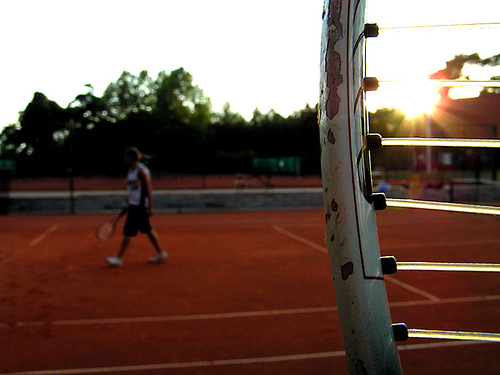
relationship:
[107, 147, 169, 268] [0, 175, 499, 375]
man on tennis court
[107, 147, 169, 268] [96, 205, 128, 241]
man has tennis racket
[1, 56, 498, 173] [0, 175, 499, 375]
trees behind tennis court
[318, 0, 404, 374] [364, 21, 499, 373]
pole has cables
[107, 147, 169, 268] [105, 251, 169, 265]
man has sneakers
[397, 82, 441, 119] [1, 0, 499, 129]
sun in sky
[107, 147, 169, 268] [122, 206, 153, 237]
man has shorts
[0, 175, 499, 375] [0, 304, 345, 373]
tennis court has white lines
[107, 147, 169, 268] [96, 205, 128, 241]
man holding tennis racket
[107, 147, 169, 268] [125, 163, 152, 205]
man wearing shirt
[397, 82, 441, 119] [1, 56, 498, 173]
sun behind trees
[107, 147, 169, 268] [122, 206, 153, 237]
man wearing shorts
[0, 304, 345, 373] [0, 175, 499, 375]
white lines on tennis court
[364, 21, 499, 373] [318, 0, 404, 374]
cables hooked to pole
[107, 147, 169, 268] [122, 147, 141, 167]
man has head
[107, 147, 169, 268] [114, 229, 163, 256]
man has legs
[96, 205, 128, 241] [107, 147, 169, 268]
tennis racket held by man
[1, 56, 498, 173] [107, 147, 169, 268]
trees behind man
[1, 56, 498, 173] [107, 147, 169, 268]
trees above man